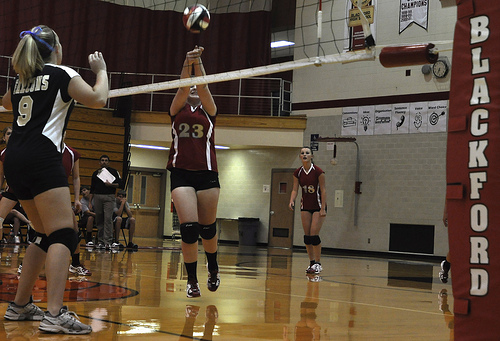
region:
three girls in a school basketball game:
[4, 24, 328, 334]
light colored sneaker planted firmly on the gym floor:
[37, 307, 96, 337]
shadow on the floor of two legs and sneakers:
[179, 305, 219, 339]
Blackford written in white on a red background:
[467, 13, 493, 296]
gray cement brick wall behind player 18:
[291, 116, 444, 254]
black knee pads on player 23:
[178, 219, 220, 244]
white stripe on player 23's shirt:
[205, 111, 216, 170]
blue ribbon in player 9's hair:
[16, 26, 53, 53]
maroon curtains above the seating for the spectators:
[0, 1, 295, 116]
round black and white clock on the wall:
[431, 58, 451, 81]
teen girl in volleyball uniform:
[282, 144, 336, 279]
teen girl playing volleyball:
[159, 40, 239, 298]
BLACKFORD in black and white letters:
[460, 10, 492, 309]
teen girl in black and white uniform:
[1, 18, 113, 340]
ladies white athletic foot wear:
[3, 298, 93, 339]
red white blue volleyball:
[175, 4, 212, 36]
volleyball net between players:
[1, 2, 384, 119]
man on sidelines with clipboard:
[87, 153, 126, 260]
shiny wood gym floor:
[0, 239, 497, 339]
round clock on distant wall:
[430, 58, 452, 82]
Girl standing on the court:
[287, 121, 333, 336]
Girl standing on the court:
[152, 27, 234, 303]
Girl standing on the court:
[7, 11, 114, 339]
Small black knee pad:
[307, 225, 323, 250]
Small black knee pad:
[297, 230, 310, 250]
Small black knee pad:
[195, 215, 233, 255]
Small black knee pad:
[167, 217, 201, 252]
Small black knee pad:
[37, 218, 87, 257]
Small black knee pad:
[25, 228, 56, 252]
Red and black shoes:
[162, 263, 236, 307]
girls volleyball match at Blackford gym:
[3, 2, 498, 339]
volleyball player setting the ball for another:
[166, 2, 219, 295]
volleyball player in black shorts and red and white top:
[286, 145, 326, 275]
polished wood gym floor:
[0, 235, 450, 335]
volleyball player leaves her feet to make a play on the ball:
[165, 5, 220, 296]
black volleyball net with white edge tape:
[0, 0, 448, 97]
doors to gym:
[125, 165, 166, 237]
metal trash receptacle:
[237, 217, 260, 245]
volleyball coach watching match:
[89, 155, 120, 249]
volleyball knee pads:
[178, 221, 215, 241]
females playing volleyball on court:
[5, 8, 363, 331]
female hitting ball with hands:
[158, 6, 239, 293]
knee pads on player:
[173, 203, 222, 241]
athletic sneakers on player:
[179, 273, 226, 297]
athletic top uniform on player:
[171, 119, 208, 141]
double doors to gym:
[124, 169, 162, 226]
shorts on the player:
[158, 168, 227, 193]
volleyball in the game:
[172, 0, 219, 31]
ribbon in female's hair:
[14, 25, 56, 46]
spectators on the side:
[0, 127, 145, 248]